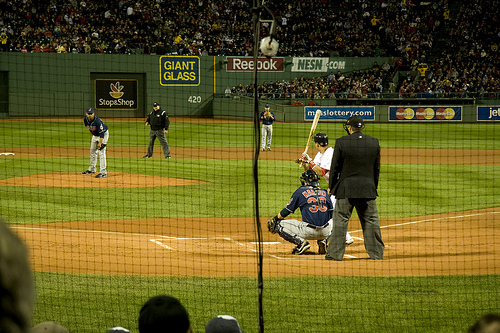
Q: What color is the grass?
A: Green.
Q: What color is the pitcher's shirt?
A: Blue.